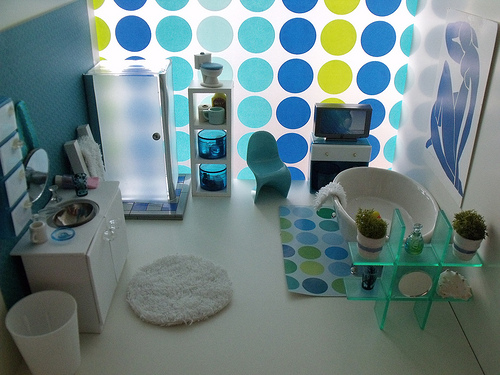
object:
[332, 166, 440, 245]
mini bath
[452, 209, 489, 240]
plants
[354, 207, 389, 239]
plants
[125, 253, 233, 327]
rug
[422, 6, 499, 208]
painting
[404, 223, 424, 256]
vase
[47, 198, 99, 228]
sink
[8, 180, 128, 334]
counter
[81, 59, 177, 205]
glass shower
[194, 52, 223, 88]
toilet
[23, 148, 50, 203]
mirror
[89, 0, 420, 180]
wall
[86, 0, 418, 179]
glass wall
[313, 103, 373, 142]
tv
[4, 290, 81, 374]
trash bin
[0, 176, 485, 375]
floor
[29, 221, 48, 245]
mug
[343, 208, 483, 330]
glass shelf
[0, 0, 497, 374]
bathroom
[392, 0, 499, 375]
wall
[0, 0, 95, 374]
wall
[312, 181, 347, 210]
towel